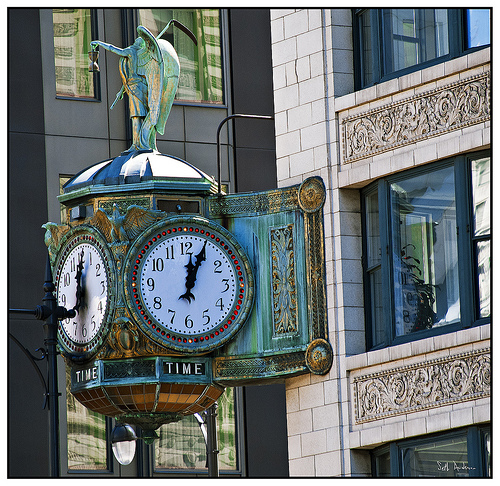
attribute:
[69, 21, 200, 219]
statue — green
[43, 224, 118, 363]
clock — white, black, green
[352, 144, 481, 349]
window — design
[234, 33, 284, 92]
wall — grey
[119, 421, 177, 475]
post — black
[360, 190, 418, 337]
curtain — green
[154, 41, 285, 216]
building — tall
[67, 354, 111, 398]
time — written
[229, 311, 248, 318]
dog — red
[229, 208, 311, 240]
green — together